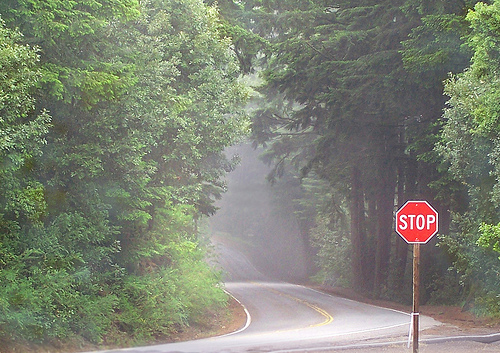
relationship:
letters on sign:
[397, 213, 438, 232] [392, 197, 441, 244]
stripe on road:
[275, 285, 336, 323] [55, 264, 435, 352]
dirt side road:
[323, 279, 493, 336] [55, 264, 435, 352]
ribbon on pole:
[406, 311, 418, 347] [406, 241, 426, 352]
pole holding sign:
[406, 241, 426, 352] [392, 197, 441, 244]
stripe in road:
[275, 285, 336, 323] [55, 264, 435, 352]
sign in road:
[392, 197, 441, 244] [55, 264, 435, 352]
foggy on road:
[183, 137, 327, 288] [55, 264, 435, 352]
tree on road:
[226, 2, 447, 300] [55, 264, 435, 352]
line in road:
[218, 279, 254, 338] [55, 264, 435, 352]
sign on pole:
[392, 197, 441, 244] [406, 241, 426, 352]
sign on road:
[392, 197, 441, 244] [55, 264, 435, 352]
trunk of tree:
[366, 165, 397, 288] [226, 2, 447, 300]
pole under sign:
[406, 241, 426, 352] [392, 197, 441, 244]